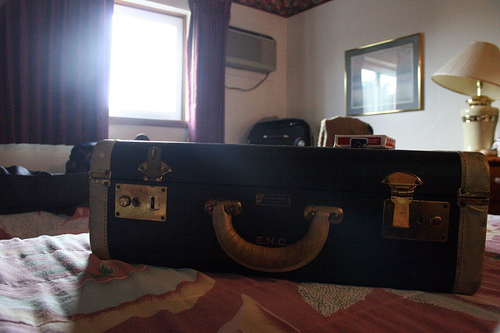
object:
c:
[277, 237, 290, 246]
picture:
[345, 34, 424, 116]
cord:
[226, 69, 270, 95]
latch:
[383, 172, 423, 229]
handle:
[203, 196, 345, 273]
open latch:
[125, 138, 192, 183]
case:
[87, 137, 490, 294]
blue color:
[97, 288, 131, 305]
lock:
[108, 183, 179, 223]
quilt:
[109, 278, 269, 318]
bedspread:
[0, 217, 499, 329]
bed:
[0, 183, 499, 329]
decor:
[344, 32, 429, 120]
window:
[112, 3, 187, 122]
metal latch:
[377, 170, 426, 232]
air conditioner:
[221, 22, 279, 92]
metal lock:
[375, 169, 457, 244]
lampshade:
[398, 40, 500, 122]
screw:
[304, 197, 346, 226]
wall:
[229, 0, 500, 221]